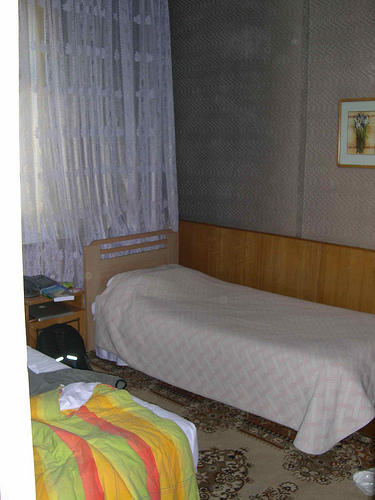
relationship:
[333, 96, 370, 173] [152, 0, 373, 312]
portrait hanging on wall\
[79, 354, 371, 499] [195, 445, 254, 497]
carpet has design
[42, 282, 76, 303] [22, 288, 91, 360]
book on top of table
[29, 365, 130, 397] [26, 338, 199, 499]
blanket on top of bed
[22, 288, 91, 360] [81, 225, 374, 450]
table beside bed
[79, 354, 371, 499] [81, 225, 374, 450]
carpet underneath bed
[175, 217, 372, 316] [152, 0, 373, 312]
paneling on bottom of wall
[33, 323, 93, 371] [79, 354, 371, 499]
bag on top of carpet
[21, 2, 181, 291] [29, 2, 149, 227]
curtain hanging on window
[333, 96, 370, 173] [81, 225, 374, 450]
portrait hanging over bed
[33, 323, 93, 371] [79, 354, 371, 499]
bag sitting on carpet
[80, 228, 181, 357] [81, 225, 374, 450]
headboard at top of bed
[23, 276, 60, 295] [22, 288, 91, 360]
phone on top of table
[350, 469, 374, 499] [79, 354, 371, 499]
object laying on top of carpet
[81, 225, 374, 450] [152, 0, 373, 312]
bed against wall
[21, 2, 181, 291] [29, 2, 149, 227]
curtain covers window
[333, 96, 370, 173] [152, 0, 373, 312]
portrait on side of wall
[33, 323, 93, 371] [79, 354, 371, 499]
bag lying on carpet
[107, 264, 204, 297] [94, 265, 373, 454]
pillow underneath spread